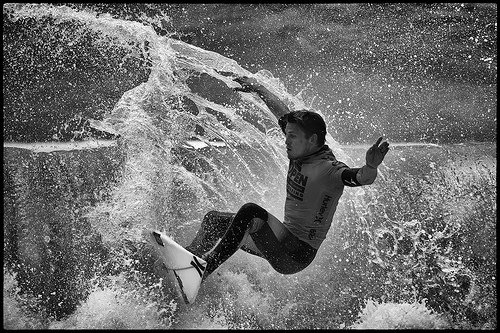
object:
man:
[186, 75, 390, 278]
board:
[148, 229, 208, 304]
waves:
[8, 135, 278, 201]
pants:
[185, 201, 318, 275]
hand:
[366, 136, 389, 168]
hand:
[232, 75, 261, 94]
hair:
[286, 110, 326, 148]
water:
[4, 6, 376, 309]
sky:
[202, 11, 489, 138]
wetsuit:
[185, 148, 361, 276]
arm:
[254, 83, 292, 118]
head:
[284, 109, 327, 161]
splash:
[100, 183, 152, 237]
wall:
[20, 8, 180, 217]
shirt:
[282, 147, 347, 252]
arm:
[341, 165, 378, 188]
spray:
[12, 50, 71, 107]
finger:
[375, 137, 384, 146]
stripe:
[193, 255, 210, 270]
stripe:
[190, 259, 203, 279]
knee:
[239, 200, 260, 226]